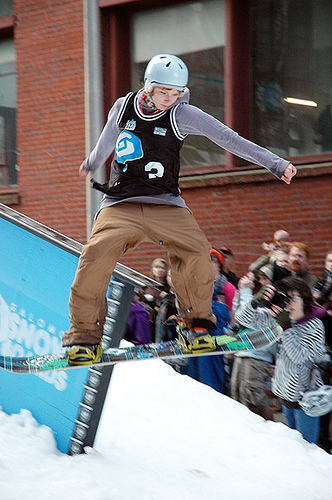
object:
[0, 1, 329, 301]
building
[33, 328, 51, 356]
words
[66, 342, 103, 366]
left footing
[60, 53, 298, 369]
rider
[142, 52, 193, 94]
helmet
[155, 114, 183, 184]
vest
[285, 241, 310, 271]
red hair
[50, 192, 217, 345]
pants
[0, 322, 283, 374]
snowboard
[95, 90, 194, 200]
jersey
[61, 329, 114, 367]
boot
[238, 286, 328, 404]
coat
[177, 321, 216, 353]
footing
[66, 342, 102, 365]
footing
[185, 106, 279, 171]
arm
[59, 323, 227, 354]
snow boots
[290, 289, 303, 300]
glasses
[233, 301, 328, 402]
sweater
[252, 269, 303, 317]
camera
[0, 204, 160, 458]
wall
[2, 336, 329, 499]
snow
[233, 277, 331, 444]
photographer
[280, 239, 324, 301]
man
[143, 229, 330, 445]
crowd